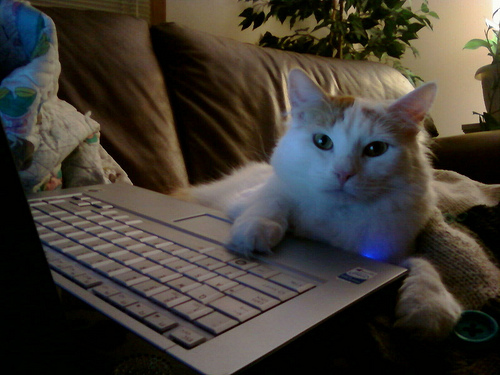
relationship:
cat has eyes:
[169, 68, 463, 338] [310, 129, 392, 160]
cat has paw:
[169, 68, 463, 338] [226, 214, 286, 256]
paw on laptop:
[226, 214, 286, 256] [0, 111, 410, 373]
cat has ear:
[169, 68, 463, 338] [285, 68, 330, 113]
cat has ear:
[169, 68, 463, 338] [385, 82, 439, 130]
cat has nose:
[169, 68, 463, 338] [329, 145, 364, 190]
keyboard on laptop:
[85, 186, 270, 329] [0, 160, 278, 355]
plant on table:
[458, 6, 500, 65] [461, 121, 499, 134]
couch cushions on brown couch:
[28, 0, 191, 197] [30, 3, 499, 266]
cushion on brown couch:
[154, 19, 416, 186] [30, 3, 499, 266]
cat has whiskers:
[169, 68, 463, 338] [357, 178, 420, 195]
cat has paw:
[193, 68, 440, 259] [226, 217, 283, 257]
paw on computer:
[226, 217, 283, 257] [2, 119, 410, 374]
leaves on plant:
[267, 7, 397, 48] [236, 0, 443, 87]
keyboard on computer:
[27, 192, 317, 350] [2, 119, 410, 374]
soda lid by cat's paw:
[449, 309, 494, 346] [397, 271, 461, 335]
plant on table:
[458, 6, 500, 65] [460, 121, 499, 131]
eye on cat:
[302, 122, 344, 155] [222, 61, 486, 335]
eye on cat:
[360, 139, 388, 158] [169, 68, 463, 338]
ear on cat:
[378, 73, 443, 128] [169, 68, 463, 338]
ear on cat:
[277, 64, 326, 119] [239, 65, 452, 263]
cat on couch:
[193, 68, 440, 259] [23, 4, 495, 329]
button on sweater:
[455, 303, 488, 344] [403, 195, 494, 370]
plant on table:
[448, 16, 498, 111] [459, 120, 499, 135]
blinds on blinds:
[35, 0, 156, 17] [35, 1, 153, 15]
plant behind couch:
[240, 0, 426, 66] [27, 7, 497, 244]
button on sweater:
[453, 310, 499, 342] [410, 296, 498, 372]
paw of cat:
[226, 214, 286, 256] [196, 90, 498, 300]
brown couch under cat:
[30, 3, 499, 266] [225, 67, 429, 209]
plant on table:
[458, 6, 500, 65] [453, 107, 498, 136]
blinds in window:
[35, 1, 153, 15] [102, 33, 247, 159]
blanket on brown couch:
[1, 0, 133, 197] [30, 3, 499, 266]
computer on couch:
[0, 119, 410, 374] [26, 4, 498, 192]